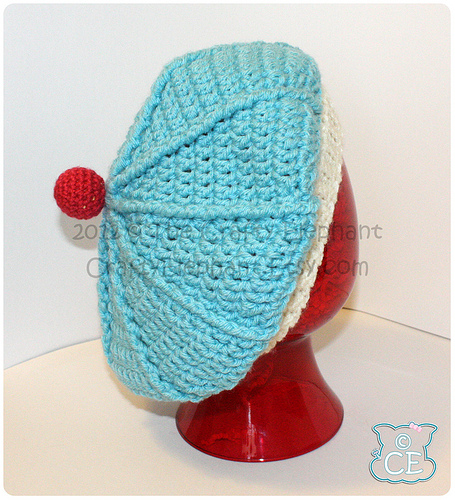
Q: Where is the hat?
A: On a head.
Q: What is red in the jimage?
A: The rest for the hat.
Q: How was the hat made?
A: By crocheting.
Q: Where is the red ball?
A: On the top of the hat.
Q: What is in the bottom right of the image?
A: The design of the company.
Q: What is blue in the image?
A: The hat.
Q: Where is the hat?
A: Next to a corner.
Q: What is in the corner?
A: A hat.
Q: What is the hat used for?
A: For a woman.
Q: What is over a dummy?
A: A hat.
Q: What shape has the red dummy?
A: Round.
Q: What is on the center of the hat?
A: A small ball.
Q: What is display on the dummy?
A: A hat.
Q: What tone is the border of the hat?
A: White.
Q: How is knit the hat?
A: Crochet.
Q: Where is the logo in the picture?
A: On the corner.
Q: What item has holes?
A: The hat.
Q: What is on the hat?
A: The lines.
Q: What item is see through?
A: The mannequin.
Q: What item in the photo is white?
A: The trim on the hat.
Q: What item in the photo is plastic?
A: The maniquin.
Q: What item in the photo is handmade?
A: The hat.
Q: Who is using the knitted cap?
A: No one.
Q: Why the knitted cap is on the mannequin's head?
A: For display.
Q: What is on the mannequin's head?
A: A knitted cap.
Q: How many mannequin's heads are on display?
A: One.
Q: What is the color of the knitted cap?
A: Blue.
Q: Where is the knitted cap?
A: On mannequin's head.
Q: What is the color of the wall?
A: White.